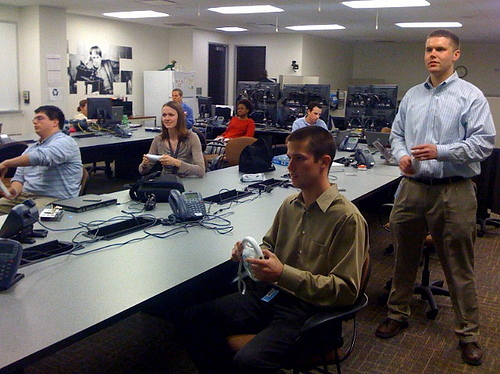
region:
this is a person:
[194, 100, 379, 368]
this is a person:
[380, 26, 498, 371]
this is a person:
[125, 93, 234, 191]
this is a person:
[13, 97, 93, 240]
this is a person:
[158, 83, 203, 136]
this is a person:
[212, 85, 274, 188]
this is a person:
[277, 80, 343, 170]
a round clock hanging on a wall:
[453, 62, 470, 79]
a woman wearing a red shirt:
[222, 117, 259, 137]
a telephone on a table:
[165, 182, 210, 223]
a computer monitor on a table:
[85, 95, 114, 120]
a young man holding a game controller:
[234, 125, 334, 289]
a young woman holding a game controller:
[137, 105, 205, 174]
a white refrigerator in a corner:
[140, 69, 197, 120]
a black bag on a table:
[241, 133, 281, 173]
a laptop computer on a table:
[55, 191, 112, 211]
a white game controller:
[240, 229, 267, 280]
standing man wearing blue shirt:
[368, 28, 499, 358]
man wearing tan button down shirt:
[228, 122, 375, 369]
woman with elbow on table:
[139, 99, 206, 179]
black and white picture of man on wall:
[62, 39, 138, 99]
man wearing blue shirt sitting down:
[1, 101, 85, 208]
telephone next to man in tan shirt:
[165, 179, 212, 230]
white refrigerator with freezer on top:
[139, 63, 201, 128]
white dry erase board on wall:
[0, 16, 27, 120]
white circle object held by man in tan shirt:
[237, 233, 267, 286]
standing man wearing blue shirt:
[373, 25, 498, 348]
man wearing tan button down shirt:
[227, 121, 367, 371]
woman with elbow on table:
[131, 100, 206, 180]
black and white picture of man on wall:
[65, 31, 136, 96]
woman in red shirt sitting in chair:
[205, 95, 252, 165]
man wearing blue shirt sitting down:
[0, 100, 81, 207]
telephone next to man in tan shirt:
[161, 180, 208, 227]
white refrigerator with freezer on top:
[137, 65, 199, 135]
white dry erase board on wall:
[0, 7, 21, 122]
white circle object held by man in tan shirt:
[233, 230, 270, 290]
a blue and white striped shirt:
[390, 72, 497, 175]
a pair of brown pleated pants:
[385, 176, 482, 342]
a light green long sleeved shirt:
[258, 183, 368, 307]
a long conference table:
[0, 141, 403, 371]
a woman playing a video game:
[136, 101, 206, 177]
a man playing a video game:
[2, 105, 83, 200]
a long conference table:
[1, 124, 159, 156]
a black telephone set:
[352, 146, 376, 166]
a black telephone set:
[338, 131, 359, 151]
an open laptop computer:
[370, 138, 396, 164]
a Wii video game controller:
[237, 236, 267, 284]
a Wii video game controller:
[145, 152, 160, 161]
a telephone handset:
[167, 186, 206, 221]